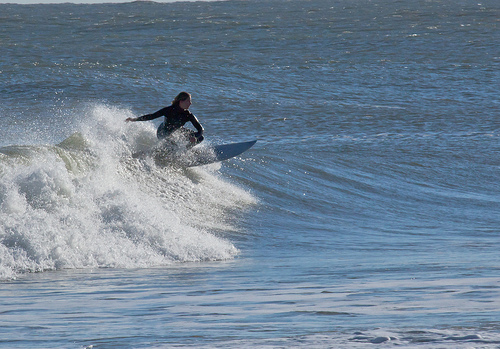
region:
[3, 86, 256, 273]
surfer at side of white wave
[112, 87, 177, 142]
arm swung back with hand in water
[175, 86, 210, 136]
surfer looking forward with bent elbow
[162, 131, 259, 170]
blue surfboard tipping up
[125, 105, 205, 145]
surfer wearing dark wetsuit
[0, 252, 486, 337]
flat blue water in front of wave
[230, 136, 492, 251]
curve of blue water toward surfboard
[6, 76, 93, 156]
drops of water behind wave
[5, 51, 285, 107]
lighter blue curve of water behind surfer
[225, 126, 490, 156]
line of water to side of surfboard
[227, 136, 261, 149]
The tip of the surfboard.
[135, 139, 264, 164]
The surfboard the lady is riding.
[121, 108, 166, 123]
The lady's left arm.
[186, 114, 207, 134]
The lady's right arm.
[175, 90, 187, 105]
The short hair of the lady.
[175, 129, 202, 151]
The knees of the surfer.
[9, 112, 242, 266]
The waves the lady is riding.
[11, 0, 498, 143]
The water in the distance.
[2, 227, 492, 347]
The water in front of the surfer.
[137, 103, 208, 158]
The wet suit the surfer is wearing.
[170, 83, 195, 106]
Person has brown hair.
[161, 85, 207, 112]
Person has long hair.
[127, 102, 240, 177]
Person wearing wet suit.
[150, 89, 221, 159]
Person's wet suit is black.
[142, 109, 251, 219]
Person is bending legs.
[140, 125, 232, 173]
Person is standing on surf board.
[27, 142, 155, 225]
Top of wave is white.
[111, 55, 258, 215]
Person is surfing in water.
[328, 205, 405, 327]
Water is blue in color.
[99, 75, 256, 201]
Person is riding a wave.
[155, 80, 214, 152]
this is a lady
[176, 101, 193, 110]
the lady is light skinned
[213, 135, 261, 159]
this is a surfboard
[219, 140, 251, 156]
the board is blue in color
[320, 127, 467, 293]
this is a water body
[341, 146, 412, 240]
the water is calm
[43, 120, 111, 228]
this is a wave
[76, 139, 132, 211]
the wave is white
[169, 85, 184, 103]
this is the hair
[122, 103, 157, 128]
this is the hand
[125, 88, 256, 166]
surfer riding a wave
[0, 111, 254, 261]
a large wave breaking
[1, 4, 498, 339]
clear blue ocean water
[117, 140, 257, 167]
blue surfboard in the water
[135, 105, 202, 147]
the surfer's black wetsuit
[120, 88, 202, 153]
female surfer with long hair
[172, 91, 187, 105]
the surfer's long dark hair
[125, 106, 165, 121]
the surfer's right arm extended back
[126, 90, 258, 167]
surfer crouching on her surfboard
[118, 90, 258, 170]
woman on surfboard on top of a wave